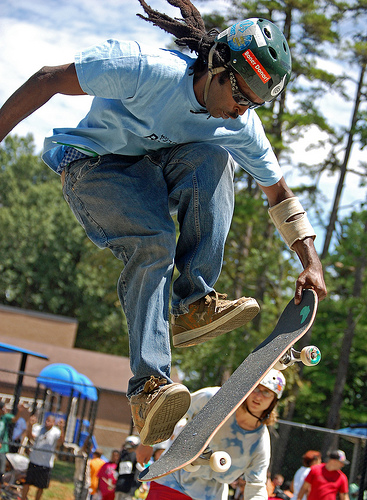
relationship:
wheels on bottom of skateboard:
[180, 336, 321, 477] [133, 282, 321, 487]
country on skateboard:
[296, 303, 311, 325] [133, 282, 321, 487]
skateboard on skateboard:
[137, 289, 321, 482] [133, 282, 321, 487]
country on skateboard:
[300, 306, 310, 324] [137, 289, 321, 482]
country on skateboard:
[296, 303, 311, 325] [137, 289, 321, 482]